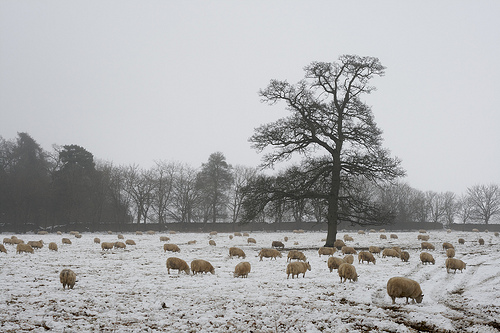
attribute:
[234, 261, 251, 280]
sheep — white, grazing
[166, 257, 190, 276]
sheep — white, grazing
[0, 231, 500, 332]
snow — fresh, covering field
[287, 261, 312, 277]
sheep — white, grazing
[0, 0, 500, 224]
sky — cloudy, gray, featureless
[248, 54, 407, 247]
tree — large, leafless, solitary, a windbreak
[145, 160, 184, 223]
tree — bare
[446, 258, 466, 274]
sheep — grazing, herd